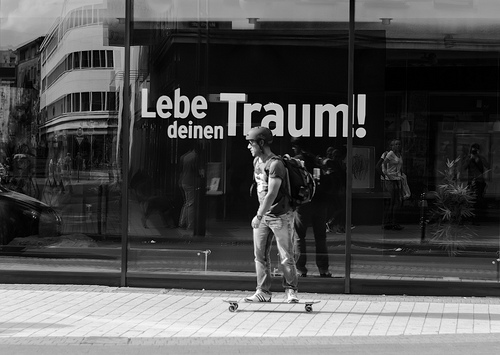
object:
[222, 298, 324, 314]
board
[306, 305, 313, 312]
wheel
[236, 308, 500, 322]
shadow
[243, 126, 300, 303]
man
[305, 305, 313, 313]
wheels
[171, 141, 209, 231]
reflection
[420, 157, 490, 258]
plant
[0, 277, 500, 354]
floor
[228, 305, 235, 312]
wheel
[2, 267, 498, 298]
edge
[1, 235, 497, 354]
road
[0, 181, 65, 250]
car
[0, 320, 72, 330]
shadow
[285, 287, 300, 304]
shoe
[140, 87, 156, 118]
words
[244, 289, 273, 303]
shoe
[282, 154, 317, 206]
backpack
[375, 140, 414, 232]
reflection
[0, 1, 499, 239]
building